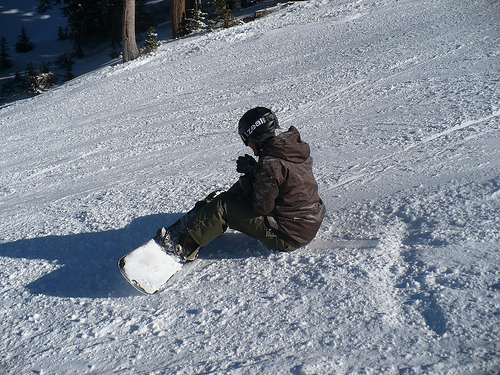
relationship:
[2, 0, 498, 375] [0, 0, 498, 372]
snow on hill side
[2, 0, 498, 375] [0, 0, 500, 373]
snow covering hillside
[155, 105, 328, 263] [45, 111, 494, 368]
man sitting in snow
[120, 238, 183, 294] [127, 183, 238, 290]
snow covering snow board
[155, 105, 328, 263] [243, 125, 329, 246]
man wearing jacket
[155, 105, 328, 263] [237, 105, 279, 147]
man wearing helmet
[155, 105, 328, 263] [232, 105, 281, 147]
man wearing helmet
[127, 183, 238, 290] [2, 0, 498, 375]
snow board sitting on top of snow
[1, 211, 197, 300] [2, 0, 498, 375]
shadow casted on snow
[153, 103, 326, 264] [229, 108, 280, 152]
woman wearing helmet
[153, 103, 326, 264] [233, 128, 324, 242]
woman wearing brown coat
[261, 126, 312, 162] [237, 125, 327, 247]
hood attached to brown coat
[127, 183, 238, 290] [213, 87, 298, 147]
snow board wearing helmet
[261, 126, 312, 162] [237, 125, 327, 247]
hood on brown coat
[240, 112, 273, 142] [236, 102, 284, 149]
strap on helmet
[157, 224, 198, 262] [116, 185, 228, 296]
boot on snowboard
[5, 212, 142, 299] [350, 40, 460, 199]
shadow on snow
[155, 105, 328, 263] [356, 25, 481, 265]
man in snow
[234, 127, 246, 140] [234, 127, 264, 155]
goggles on face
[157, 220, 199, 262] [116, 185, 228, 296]
feet on snowboard